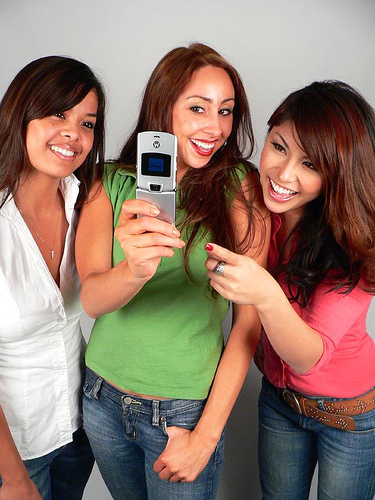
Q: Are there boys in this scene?
A: No, there are no boys.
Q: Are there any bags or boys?
A: No, there are no boys or bags.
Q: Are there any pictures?
A: No, there are no pictures.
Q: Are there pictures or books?
A: No, there are no pictures or books.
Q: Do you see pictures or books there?
A: No, there are no pictures or books.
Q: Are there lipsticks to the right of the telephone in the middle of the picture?
A: Yes, there is a lipstick to the right of the phone.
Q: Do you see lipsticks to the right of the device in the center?
A: Yes, there is a lipstick to the right of the phone.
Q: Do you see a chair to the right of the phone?
A: No, there is a lipstick to the right of the phone.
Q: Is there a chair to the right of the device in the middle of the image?
A: No, there is a lipstick to the right of the phone.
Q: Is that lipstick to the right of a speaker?
A: No, the lipstick is to the right of the phone.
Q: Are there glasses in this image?
A: No, there are no glasses.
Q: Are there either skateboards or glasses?
A: No, there are no glasses or skateboards.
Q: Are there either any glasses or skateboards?
A: No, there are no glasses or skateboards.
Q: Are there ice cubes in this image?
A: No, there are no ice cubes.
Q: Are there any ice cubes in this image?
A: No, there are no ice cubes.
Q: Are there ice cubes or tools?
A: No, there are no ice cubes or tools.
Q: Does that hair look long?
A: Yes, the hair is long.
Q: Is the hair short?
A: No, the hair is long.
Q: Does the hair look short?
A: No, the hair is long.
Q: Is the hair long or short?
A: The hair is long.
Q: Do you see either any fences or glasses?
A: No, there are no fences or glasses.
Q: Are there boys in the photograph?
A: No, there are no boys.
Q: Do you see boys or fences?
A: No, there are no boys or fences.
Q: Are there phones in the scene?
A: Yes, there is a phone.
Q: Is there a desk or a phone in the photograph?
A: Yes, there is a phone.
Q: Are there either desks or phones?
A: Yes, there is a phone.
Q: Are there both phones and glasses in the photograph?
A: No, there is a phone but no glasses.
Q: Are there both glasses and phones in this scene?
A: No, there is a phone but no glasses.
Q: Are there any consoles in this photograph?
A: No, there are no consoles.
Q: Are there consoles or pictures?
A: No, there are no consoles or pictures.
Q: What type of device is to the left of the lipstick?
A: The device is a phone.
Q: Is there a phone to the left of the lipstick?
A: Yes, there is a phone to the left of the lipstick.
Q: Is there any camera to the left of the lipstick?
A: No, there is a phone to the left of the lipstick.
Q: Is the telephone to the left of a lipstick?
A: Yes, the telephone is to the left of a lipstick.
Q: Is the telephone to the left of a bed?
A: No, the telephone is to the left of a lipstick.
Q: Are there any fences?
A: No, there are no fences.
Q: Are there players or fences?
A: No, there are no fences or players.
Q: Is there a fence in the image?
A: No, there are no fences.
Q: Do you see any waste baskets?
A: No, there are no waste baskets.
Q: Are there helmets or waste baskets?
A: No, there are no waste baskets or helmets.